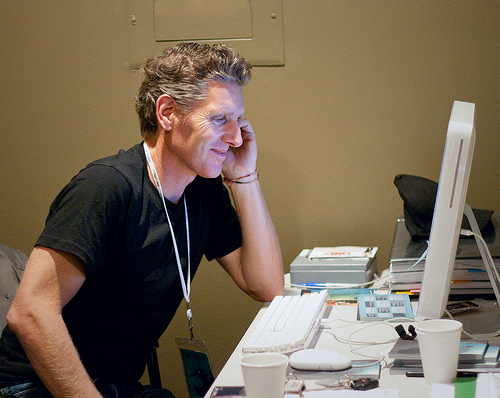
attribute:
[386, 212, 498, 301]
binder — large, paper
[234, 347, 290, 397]
cup — white, paper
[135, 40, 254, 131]
hair — black and white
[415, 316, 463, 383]
paper cup — white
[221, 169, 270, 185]
bracelets — colorful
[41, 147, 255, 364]
shirt — black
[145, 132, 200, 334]
lanyard — white, name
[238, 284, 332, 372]
keyboard — white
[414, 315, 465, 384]
plastic cup — white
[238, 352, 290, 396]
plastic cup — white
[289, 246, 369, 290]
books — thick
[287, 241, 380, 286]
box — silver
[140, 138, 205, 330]
lanyard — white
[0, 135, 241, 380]
shirt — black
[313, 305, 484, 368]
cords — white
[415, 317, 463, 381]
cup — white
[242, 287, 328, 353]
keyboard — white